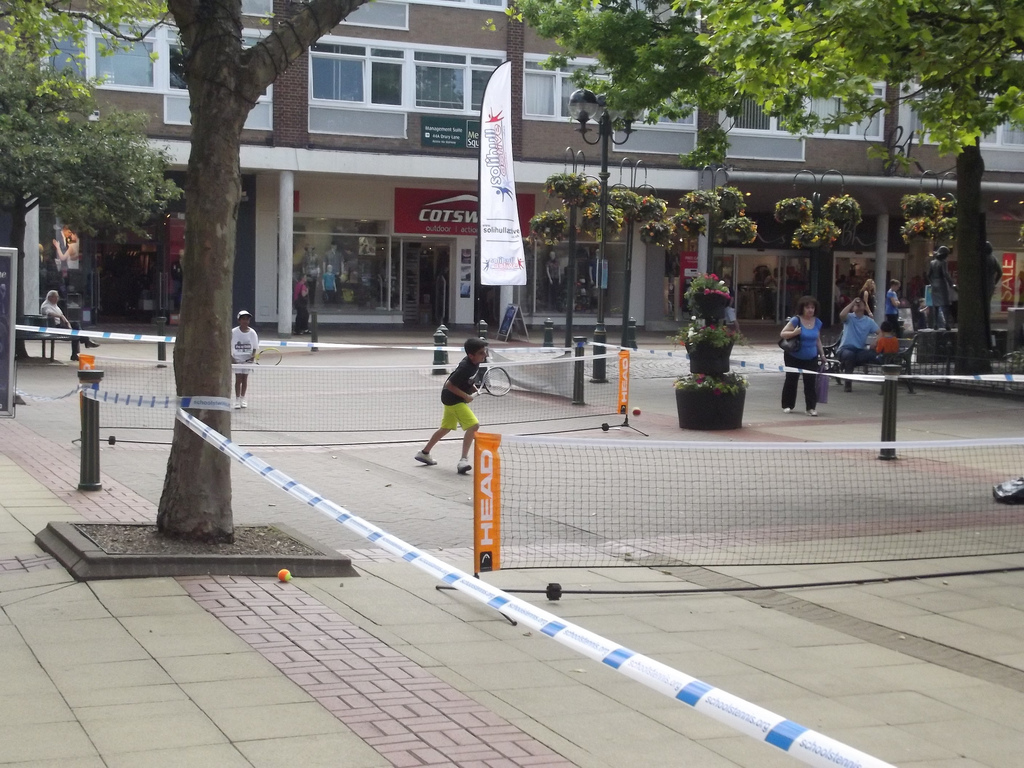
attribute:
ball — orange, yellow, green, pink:
[279, 565, 297, 587]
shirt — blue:
[785, 315, 828, 361]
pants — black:
[785, 354, 821, 412]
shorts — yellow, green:
[445, 398, 479, 438]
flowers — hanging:
[513, 155, 999, 266]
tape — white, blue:
[5, 322, 1022, 766]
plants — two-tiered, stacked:
[678, 275, 754, 434]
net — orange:
[20, 316, 662, 437]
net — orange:
[470, 421, 1022, 589]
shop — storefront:
[4, 3, 1023, 349]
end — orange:
[457, 420, 535, 596]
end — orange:
[604, 344, 638, 422]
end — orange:
[64, 349, 106, 392]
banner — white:
[477, 58, 539, 291]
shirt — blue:
[843, 310, 886, 354]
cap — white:
[231, 308, 255, 320]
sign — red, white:
[397, 189, 1023, 319]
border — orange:
[67, 345, 108, 377]